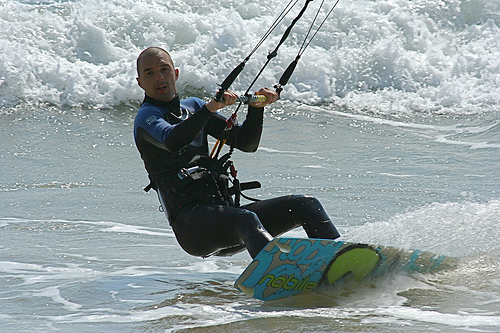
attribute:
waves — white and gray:
[2, 3, 498, 132]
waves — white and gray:
[0, 9, 499, 115]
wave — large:
[9, 1, 498, 137]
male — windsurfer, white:
[127, 44, 339, 252]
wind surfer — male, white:
[206, 0, 449, 287]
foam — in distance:
[319, 19, 466, 110]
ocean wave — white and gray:
[2, 212, 177, 240]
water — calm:
[4, 97, 499, 329]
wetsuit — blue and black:
[132, 93, 344, 260]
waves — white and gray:
[5, 2, 498, 119]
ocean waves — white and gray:
[302, 27, 475, 173]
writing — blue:
[263, 274, 321, 296]